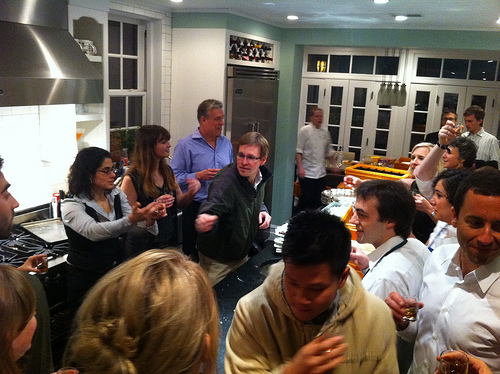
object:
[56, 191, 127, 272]
vest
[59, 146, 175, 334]
lady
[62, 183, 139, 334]
dress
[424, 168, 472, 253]
woman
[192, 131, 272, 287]
man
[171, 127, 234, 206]
shirt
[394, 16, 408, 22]
ceiling light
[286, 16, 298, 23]
ceiling light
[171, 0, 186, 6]
ceiling light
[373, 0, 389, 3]
ceiling light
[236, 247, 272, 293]
ground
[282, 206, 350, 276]
hair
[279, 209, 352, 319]
head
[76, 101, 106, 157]
shelves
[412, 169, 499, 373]
man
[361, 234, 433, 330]
shirt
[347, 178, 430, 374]
man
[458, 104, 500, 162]
man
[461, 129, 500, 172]
shirt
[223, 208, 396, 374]
man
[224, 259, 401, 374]
hoodie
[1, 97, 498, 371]
people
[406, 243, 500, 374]
shirt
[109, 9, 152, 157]
window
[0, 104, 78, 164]
light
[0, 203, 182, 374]
stove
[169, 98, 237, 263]
man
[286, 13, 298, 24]
light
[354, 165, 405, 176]
vegetable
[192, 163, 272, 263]
jacket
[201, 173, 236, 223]
arm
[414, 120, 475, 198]
person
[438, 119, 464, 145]
hand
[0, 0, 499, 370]
kitchen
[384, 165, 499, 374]
man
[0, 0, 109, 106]
hood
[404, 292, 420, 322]
shot glass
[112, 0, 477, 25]
ceiling